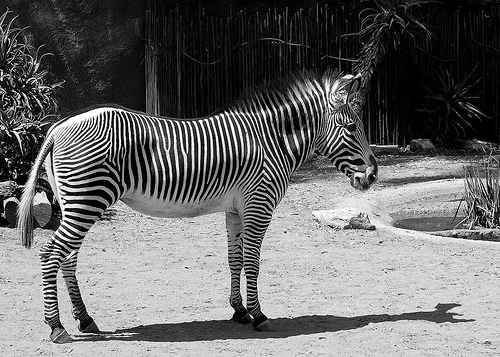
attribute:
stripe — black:
[333, 156, 366, 173]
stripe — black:
[326, 151, 351, 162]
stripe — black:
[224, 108, 240, 191]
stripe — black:
[192, 120, 204, 212]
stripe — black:
[61, 196, 108, 211]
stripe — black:
[60, 201, 90, 256]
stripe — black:
[275, 96, 300, 162]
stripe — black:
[52, 187, 127, 196]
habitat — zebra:
[4, 3, 495, 351]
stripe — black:
[197, 123, 210, 208]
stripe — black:
[276, 91, 304, 167]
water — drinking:
[395, 181, 472, 242]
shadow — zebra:
[72, 289, 490, 343]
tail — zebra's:
[10, 131, 50, 246]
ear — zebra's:
[328, 73, 354, 106]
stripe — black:
[47, 220, 81, 232]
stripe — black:
[51, 234, 74, 254]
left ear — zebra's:
[339, 77, 382, 116]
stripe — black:
[59, 209, 90, 238]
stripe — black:
[58, 177, 126, 199]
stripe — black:
[61, 201, 106, 221]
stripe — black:
[39, 280, 61, 295]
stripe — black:
[240, 262, 257, 278]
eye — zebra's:
[339, 120, 356, 137]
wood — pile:
[1, 181, 62, 229]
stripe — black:
[50, 226, 84, 236]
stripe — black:
[328, 140, 358, 155]